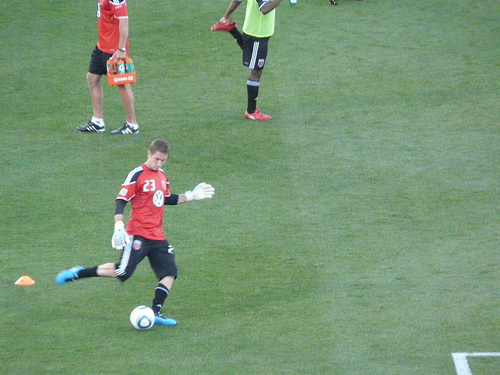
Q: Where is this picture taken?
A: Soccer field.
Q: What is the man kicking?
A: Soccer ball.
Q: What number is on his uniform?
A: 23.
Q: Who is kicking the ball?
A: Goalie.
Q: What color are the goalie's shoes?
A: Blue.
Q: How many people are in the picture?
A: Three.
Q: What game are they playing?
A: Soccer.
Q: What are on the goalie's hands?
A: Gloves.